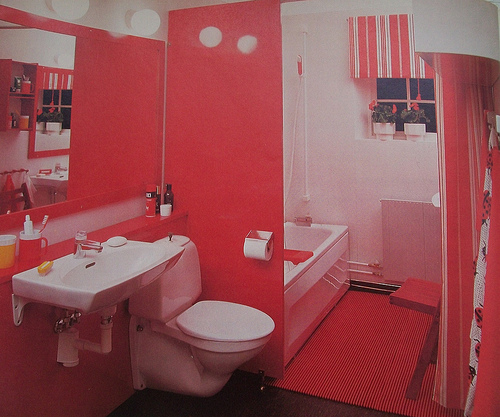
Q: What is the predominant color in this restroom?
A: Red.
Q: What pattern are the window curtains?
A: Stripes.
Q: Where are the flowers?
A: Windowsill.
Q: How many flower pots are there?
A: 2.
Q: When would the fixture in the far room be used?
A: To take a bath.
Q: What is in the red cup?
A: Toothpaste and toothbrush.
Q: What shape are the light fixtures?
A: Round.